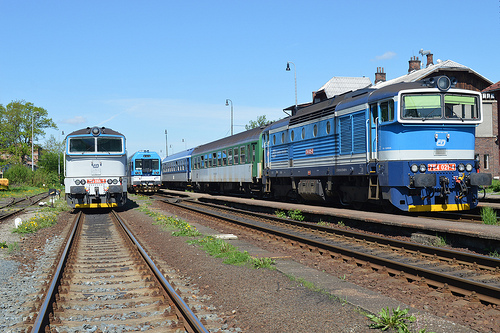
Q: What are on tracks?
A: Trains.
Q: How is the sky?
A: Clear and blue.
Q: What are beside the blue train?
A: Houses.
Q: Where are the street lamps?
A: On the right side of the blue train.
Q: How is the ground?
A: Cover with rocks and dirts.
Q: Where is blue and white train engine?
A: On the right of this picture.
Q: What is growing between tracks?
A: Grass.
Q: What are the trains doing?
A: Sitting on track.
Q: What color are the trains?
A: Blue.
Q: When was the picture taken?
A: Day time.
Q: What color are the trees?
A: Green.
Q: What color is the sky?
A: Blue.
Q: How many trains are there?
A: Three.